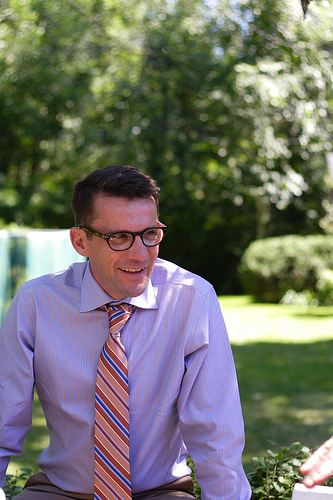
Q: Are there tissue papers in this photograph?
A: No, there are no tissue papers.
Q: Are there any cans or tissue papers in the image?
A: No, there are no tissue papers or cans.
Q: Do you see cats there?
A: No, there are no cats.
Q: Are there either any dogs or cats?
A: No, there are no cats or dogs.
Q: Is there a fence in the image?
A: No, there are no fences.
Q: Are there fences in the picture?
A: No, there are no fences.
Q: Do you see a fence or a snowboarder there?
A: No, there are no fences or snowboarders.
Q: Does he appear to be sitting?
A: Yes, the man is sitting.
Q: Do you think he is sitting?
A: Yes, the man is sitting.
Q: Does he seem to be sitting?
A: Yes, the man is sitting.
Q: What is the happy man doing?
A: The man is sitting.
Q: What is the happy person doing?
A: The man is sitting.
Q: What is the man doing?
A: The man is sitting.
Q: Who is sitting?
A: The man is sitting.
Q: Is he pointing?
A: No, the man is sitting.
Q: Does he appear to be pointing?
A: No, the man is sitting.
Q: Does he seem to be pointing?
A: No, the man is sitting.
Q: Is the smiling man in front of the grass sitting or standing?
A: The man is sitting.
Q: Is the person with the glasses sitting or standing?
A: The man is sitting.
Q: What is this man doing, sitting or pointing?
A: The man is sitting.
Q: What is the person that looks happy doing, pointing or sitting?
A: The man is sitting.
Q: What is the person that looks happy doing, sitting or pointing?
A: The man is sitting.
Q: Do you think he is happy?
A: Yes, the man is happy.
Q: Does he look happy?
A: Yes, the man is happy.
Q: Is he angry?
A: No, the man is happy.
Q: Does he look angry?
A: No, the man is happy.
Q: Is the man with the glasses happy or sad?
A: The man is happy.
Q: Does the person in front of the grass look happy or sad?
A: The man is happy.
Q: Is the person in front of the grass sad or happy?
A: The man is happy.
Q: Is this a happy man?
A: Yes, this is a happy man.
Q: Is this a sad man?
A: No, this is a happy man.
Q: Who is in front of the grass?
A: The man is in front of the grass.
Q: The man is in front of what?
A: The man is in front of the grass.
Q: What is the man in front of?
A: The man is in front of the grass.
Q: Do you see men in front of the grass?
A: Yes, there is a man in front of the grass.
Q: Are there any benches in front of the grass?
A: No, there is a man in front of the grass.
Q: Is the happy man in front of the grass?
A: Yes, the man is in front of the grass.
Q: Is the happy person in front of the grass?
A: Yes, the man is in front of the grass.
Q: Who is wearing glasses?
A: The man is wearing glasses.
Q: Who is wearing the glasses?
A: The man is wearing glasses.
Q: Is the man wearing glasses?
A: Yes, the man is wearing glasses.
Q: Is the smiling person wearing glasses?
A: Yes, the man is wearing glasses.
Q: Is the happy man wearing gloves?
A: No, the man is wearing glasses.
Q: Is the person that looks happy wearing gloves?
A: No, the man is wearing glasses.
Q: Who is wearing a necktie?
A: The man is wearing a necktie.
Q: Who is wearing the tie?
A: The man is wearing a necktie.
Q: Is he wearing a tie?
A: Yes, the man is wearing a tie.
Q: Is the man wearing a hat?
A: No, the man is wearing a tie.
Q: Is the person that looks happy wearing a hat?
A: No, the man is wearing a tie.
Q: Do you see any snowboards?
A: No, there are no snowboards.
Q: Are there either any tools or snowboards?
A: No, there are no snowboards or tools.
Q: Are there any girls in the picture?
A: No, there are no girls.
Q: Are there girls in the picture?
A: No, there are no girls.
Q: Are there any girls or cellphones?
A: No, there are no girls or cellphones.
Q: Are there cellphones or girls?
A: No, there are no girls or cellphones.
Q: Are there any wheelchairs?
A: No, there are no wheelchairs.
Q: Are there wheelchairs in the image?
A: No, there are no wheelchairs.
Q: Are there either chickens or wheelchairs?
A: No, there are no wheelchairs or chickens.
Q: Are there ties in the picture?
A: Yes, there is a tie.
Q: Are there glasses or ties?
A: Yes, there is a tie.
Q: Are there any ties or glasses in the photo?
A: Yes, there is a tie.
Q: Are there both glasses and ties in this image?
A: Yes, there are both a tie and glasses.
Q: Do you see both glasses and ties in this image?
A: Yes, there are both a tie and glasses.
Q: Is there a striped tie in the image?
A: Yes, there is a striped tie.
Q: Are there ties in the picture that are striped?
A: Yes, there is a tie that is striped.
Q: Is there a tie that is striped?
A: Yes, there is a tie that is striped.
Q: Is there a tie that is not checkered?
A: Yes, there is a striped tie.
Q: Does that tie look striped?
A: Yes, the tie is striped.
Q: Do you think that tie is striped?
A: Yes, the tie is striped.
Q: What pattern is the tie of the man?
A: The necktie is striped.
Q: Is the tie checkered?
A: No, the tie is striped.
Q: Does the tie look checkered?
A: No, the tie is striped.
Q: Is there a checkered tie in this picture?
A: No, there is a tie but it is striped.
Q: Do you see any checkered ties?
A: No, there is a tie but it is striped.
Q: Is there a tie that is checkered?
A: No, there is a tie but it is striped.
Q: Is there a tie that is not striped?
A: No, there is a tie but it is striped.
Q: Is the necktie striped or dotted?
A: The necktie is striped.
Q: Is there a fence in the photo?
A: No, there are no fences.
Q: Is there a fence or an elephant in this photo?
A: No, there are no fences or elephants.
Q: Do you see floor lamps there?
A: No, there are no floor lamps.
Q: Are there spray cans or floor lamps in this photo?
A: No, there are no floor lamps or spray cans.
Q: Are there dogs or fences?
A: No, there are no fences or dogs.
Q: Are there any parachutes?
A: No, there are no parachutes.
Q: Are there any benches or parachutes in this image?
A: No, there are no parachutes or benches.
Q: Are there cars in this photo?
A: No, there are no cars.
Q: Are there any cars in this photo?
A: No, there are no cars.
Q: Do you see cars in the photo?
A: No, there are no cars.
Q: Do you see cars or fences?
A: No, there are no cars or fences.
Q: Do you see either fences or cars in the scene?
A: No, there are no cars or fences.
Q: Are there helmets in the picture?
A: No, there are no helmets.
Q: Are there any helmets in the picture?
A: No, there are no helmets.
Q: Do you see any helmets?
A: No, there are no helmets.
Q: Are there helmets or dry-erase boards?
A: No, there are no helmets or dry-erase boards.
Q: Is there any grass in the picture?
A: Yes, there is grass.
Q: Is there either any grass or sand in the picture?
A: Yes, there is grass.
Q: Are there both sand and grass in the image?
A: No, there is grass but no sand.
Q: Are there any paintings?
A: No, there are no paintings.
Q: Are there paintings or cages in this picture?
A: No, there are no paintings or cages.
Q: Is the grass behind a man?
A: Yes, the grass is behind a man.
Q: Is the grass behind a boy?
A: No, the grass is behind a man.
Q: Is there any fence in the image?
A: No, there are no fences.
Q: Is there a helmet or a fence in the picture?
A: No, there are no fences or helmets.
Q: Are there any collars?
A: Yes, there is a collar.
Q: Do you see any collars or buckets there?
A: Yes, there is a collar.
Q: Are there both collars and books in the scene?
A: No, there is a collar but no books.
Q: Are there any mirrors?
A: No, there are no mirrors.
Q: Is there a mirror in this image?
A: No, there are no mirrors.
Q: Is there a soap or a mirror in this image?
A: No, there are no mirrors or soaps.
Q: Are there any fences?
A: No, there are no fences.